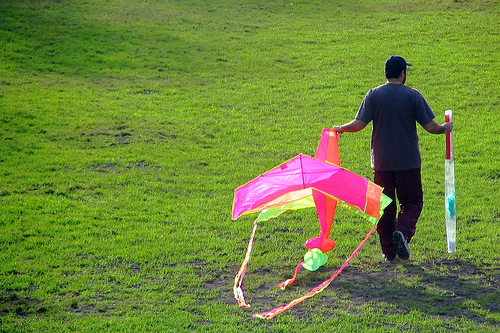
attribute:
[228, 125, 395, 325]
kite — colorful, pink, shaped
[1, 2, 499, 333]
grass — green, muddy, bright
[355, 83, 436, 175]
t-shirt — blue, gray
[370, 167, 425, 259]
pants — black, dark colored, maroon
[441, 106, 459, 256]
something — folded up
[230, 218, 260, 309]
tail — pink, yellow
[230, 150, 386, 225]
wing — pink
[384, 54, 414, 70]
cap — black, dark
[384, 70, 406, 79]
hair — dark